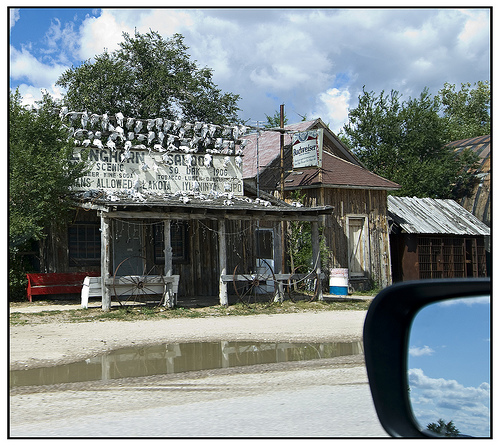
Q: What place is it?
A: It is a store.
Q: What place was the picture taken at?
A: It was taken at the store.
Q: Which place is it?
A: It is a store.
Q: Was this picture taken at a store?
A: Yes, it was taken in a store.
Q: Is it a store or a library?
A: It is a store.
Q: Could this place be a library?
A: No, it is a store.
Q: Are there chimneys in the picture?
A: No, there are no chimneys.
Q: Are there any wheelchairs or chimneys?
A: No, there are no chimneys or wheelchairs.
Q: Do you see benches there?
A: Yes, there is a bench.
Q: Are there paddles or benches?
A: Yes, there is a bench.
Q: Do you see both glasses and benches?
A: No, there is a bench but no glasses.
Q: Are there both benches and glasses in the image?
A: No, there is a bench but no glasses.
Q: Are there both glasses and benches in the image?
A: No, there is a bench but no glasses.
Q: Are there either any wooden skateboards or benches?
A: Yes, there is a wood bench.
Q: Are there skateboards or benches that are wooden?
A: Yes, the bench is wooden.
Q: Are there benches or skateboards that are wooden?
A: Yes, the bench is wooden.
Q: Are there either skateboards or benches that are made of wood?
A: Yes, the bench is made of wood.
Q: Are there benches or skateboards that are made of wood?
A: Yes, the bench is made of wood.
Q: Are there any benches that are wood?
A: Yes, there is a wood bench.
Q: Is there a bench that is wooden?
A: Yes, there is a bench that is wooden.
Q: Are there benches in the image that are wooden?
A: Yes, there is a bench that is wooden.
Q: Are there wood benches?
A: Yes, there is a bench that is made of wood.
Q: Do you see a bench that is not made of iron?
A: Yes, there is a bench that is made of wood.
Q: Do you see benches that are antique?
A: Yes, there is an antique bench.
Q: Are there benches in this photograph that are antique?
A: Yes, there is a bench that is antique.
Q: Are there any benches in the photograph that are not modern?
A: Yes, there is a antique bench.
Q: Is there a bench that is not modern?
A: Yes, there is a antique bench.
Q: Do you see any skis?
A: No, there are no skis.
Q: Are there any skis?
A: No, there are no skis.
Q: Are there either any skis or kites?
A: No, there are no skis or kites.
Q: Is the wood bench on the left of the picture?
A: Yes, the bench is on the left of the image.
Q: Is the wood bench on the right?
A: No, the bench is on the left of the image.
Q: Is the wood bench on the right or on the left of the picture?
A: The bench is on the left of the image.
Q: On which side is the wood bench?
A: The bench is on the left of the image.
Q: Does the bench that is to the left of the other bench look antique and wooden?
A: Yes, the bench is antique and wooden.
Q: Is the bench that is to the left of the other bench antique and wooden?
A: Yes, the bench is antique and wooden.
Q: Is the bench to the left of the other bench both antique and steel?
A: No, the bench is antique but wooden.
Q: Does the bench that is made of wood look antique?
A: Yes, the bench is antique.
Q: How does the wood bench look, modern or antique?
A: The bench is antique.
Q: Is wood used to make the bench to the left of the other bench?
A: Yes, the bench is made of wood.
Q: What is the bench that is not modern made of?
A: The bench is made of wood.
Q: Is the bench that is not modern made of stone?
A: No, the bench is made of wood.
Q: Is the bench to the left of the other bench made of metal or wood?
A: The bench is made of wood.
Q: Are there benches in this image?
A: Yes, there is a bench.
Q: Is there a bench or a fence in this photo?
A: Yes, there is a bench.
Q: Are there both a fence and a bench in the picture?
A: No, there is a bench but no fences.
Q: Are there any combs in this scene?
A: No, there are no combs.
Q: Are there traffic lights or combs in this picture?
A: No, there are no combs or traffic lights.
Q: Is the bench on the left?
A: Yes, the bench is on the left of the image.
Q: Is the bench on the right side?
A: No, the bench is on the left of the image.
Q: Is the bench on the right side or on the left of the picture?
A: The bench is on the left of the image.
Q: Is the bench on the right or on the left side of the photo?
A: The bench is on the left of the image.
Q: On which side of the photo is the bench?
A: The bench is on the left of the image.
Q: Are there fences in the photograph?
A: No, there are no fences.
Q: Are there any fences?
A: No, there are no fences.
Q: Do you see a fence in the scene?
A: No, there are no fences.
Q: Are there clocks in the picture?
A: No, there are no clocks.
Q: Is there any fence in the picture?
A: No, there are no fences.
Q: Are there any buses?
A: No, there are no buses.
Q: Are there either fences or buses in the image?
A: No, there are no buses or fences.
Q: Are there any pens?
A: No, there are no pens.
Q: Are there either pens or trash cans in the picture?
A: No, there are no pens or trash cans.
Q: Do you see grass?
A: Yes, there is grass.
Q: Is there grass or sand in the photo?
A: Yes, there is grass.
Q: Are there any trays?
A: No, there are no trays.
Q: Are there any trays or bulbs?
A: No, there are no trays or bulbs.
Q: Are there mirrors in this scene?
A: Yes, there is a mirror.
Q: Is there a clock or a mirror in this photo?
A: Yes, there is a mirror.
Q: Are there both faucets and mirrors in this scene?
A: No, there is a mirror but no faucets.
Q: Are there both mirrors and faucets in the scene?
A: No, there is a mirror but no faucets.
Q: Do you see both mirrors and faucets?
A: No, there is a mirror but no faucets.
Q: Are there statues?
A: No, there are no statues.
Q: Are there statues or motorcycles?
A: No, there are no statues or motorcycles.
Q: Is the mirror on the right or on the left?
A: The mirror is on the right of the image.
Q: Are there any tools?
A: No, there are no tools.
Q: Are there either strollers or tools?
A: No, there are no tools or strollers.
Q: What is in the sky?
A: The clouds are in the sky.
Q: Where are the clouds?
A: The clouds are in the sky.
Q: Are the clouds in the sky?
A: Yes, the clouds are in the sky.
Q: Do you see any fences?
A: No, there are no fences.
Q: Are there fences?
A: No, there are no fences.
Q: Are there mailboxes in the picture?
A: No, there are no mailboxes.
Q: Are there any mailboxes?
A: No, there are no mailboxes.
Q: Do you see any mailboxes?
A: No, there are no mailboxes.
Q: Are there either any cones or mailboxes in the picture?
A: No, there are no mailboxes or cones.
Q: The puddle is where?
A: The puddle is on the road.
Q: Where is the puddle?
A: The puddle is on the road.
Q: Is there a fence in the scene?
A: No, there are no fences.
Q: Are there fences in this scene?
A: No, there are no fences.